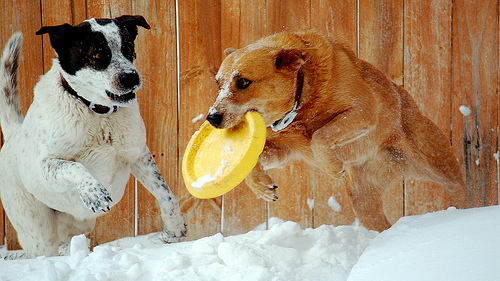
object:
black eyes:
[93, 52, 133, 59]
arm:
[309, 107, 379, 145]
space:
[181, 110, 267, 199]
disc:
[179, 110, 266, 199]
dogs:
[0, 14, 466, 258]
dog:
[0, 15, 189, 281]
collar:
[271, 66, 306, 131]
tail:
[0, 30, 25, 141]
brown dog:
[205, 27, 470, 233]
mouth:
[222, 107, 265, 134]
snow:
[0, 205, 500, 281]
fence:
[0, 0, 500, 252]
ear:
[35, 22, 72, 46]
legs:
[160, 201, 186, 229]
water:
[186, 202, 241, 233]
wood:
[432, 53, 498, 108]